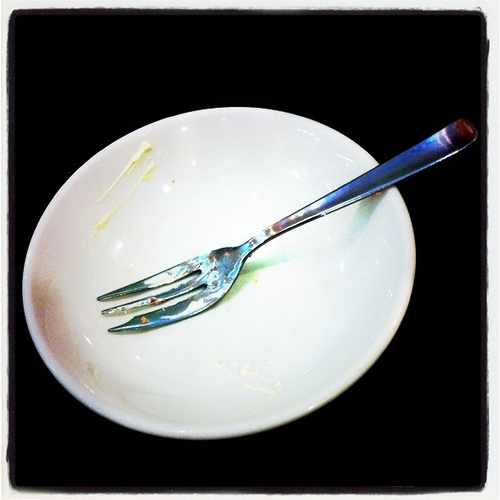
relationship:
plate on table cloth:
[9, 97, 439, 434] [14, 11, 468, 100]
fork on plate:
[94, 116, 479, 331] [9, 97, 439, 434]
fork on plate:
[94, 116, 479, 331] [22, 105, 419, 450]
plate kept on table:
[9, 97, 439, 434] [12, 16, 482, 483]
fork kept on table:
[94, 116, 479, 331] [12, 16, 482, 483]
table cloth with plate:
[8, 8, 487, 491] [22, 105, 419, 450]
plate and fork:
[22, 105, 419, 450] [94, 116, 479, 331]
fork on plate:
[93, 116, 476, 334] [19, 84, 454, 459]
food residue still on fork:
[149, 293, 159, 310] [94, 116, 479, 331]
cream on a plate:
[94, 141, 155, 235] [9, 97, 439, 434]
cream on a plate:
[94, 141, 155, 235] [22, 105, 419, 450]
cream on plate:
[94, 141, 155, 235] [22, 105, 419, 450]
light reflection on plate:
[102, 145, 322, 372] [9, 97, 439, 434]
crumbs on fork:
[140, 315, 148, 325] [94, 116, 479, 331]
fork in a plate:
[94, 116, 479, 331] [22, 105, 419, 450]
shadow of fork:
[232, 190, 388, 274] [97, 169, 421, 331]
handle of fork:
[245, 117, 480, 252] [94, 116, 479, 331]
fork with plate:
[94, 116, 479, 331] [22, 105, 419, 450]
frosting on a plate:
[376, 200, 401, 241] [22, 105, 419, 450]